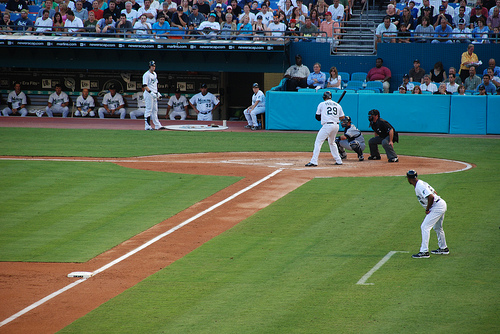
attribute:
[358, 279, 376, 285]
line — white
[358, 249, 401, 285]
line — white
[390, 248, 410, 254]
line — white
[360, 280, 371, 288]
line — white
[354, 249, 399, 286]
line — white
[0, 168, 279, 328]
line — white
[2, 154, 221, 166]
line — white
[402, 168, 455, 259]
coach — THIRD BASE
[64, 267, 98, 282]
pad — THIRD BASE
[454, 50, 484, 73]
shirt — YELLOW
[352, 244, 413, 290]
lines — WHITE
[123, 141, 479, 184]
dirt — CIRCLE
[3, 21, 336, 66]
rails — BLUE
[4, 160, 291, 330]
line — WHITE